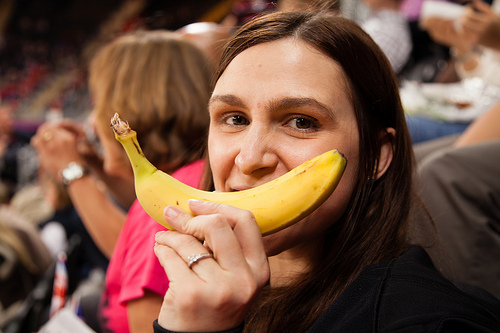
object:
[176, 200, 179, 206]
spot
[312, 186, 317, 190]
spot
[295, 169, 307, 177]
spot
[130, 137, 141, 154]
spot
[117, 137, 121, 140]
spot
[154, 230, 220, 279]
finger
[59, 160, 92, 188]
watch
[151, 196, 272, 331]
hand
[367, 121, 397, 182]
ear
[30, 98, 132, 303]
person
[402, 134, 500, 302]
pants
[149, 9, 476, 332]
woman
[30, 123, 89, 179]
hand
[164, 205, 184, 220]
nail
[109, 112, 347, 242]
banana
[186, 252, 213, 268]
ring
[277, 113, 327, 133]
eyes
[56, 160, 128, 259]
arm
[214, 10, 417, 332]
hair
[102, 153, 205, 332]
shirt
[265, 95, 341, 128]
eyebrow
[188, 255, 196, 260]
diamond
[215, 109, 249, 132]
eye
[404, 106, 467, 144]
jean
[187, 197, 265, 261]
finger